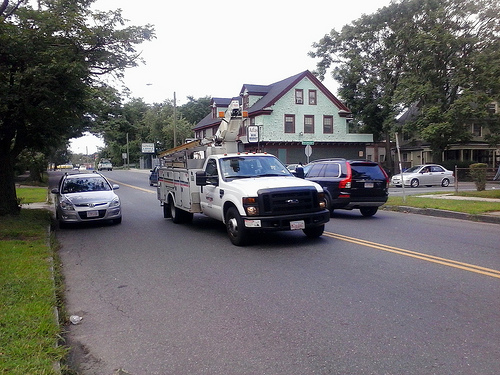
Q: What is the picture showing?
A: It is showing a road.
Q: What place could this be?
A: It is a road.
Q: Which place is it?
A: It is a road.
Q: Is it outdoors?
A: Yes, it is outdoors.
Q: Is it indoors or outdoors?
A: It is outdoors.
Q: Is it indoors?
A: No, it is outdoors.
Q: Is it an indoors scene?
A: No, it is outdoors.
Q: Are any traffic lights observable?
A: No, there are no traffic lights.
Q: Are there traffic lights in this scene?
A: No, there are no traffic lights.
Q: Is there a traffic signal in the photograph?
A: No, there are no traffic lights.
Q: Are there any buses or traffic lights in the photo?
A: No, there are no traffic lights or buses.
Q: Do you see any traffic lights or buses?
A: No, there are no traffic lights or buses.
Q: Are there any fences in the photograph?
A: No, there are no fences.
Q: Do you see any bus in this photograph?
A: No, there are no buses.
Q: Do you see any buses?
A: No, there are no buses.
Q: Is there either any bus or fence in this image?
A: No, there are no buses or fences.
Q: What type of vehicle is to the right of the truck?
A: The vehicle is a car.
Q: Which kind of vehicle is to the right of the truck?
A: The vehicle is a car.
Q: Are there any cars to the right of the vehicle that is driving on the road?
A: Yes, there is a car to the right of the truck.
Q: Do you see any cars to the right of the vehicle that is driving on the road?
A: Yes, there is a car to the right of the truck.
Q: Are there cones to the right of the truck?
A: No, there is a car to the right of the truck.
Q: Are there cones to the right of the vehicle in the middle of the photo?
A: No, there is a car to the right of the truck.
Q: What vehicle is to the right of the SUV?
A: The vehicle is a car.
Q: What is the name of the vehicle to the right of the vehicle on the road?
A: The vehicle is a car.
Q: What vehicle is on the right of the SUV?
A: The vehicle is a car.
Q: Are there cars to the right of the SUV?
A: Yes, there is a car to the right of the SUV.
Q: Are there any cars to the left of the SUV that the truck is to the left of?
A: No, the car is to the right of the SUV.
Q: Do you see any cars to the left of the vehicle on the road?
A: No, the car is to the right of the SUV.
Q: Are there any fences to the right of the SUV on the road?
A: No, there is a car to the right of the SUV.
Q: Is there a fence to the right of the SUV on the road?
A: No, there is a car to the right of the SUV.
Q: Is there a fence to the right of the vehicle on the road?
A: No, there is a car to the right of the SUV.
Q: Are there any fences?
A: No, there are no fences.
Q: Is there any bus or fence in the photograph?
A: No, there are no fences or buses.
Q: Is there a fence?
A: No, there are no fences.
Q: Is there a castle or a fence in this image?
A: No, there are no fences or castles.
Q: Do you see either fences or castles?
A: No, there are no fences or castles.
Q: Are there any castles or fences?
A: No, there are no fences or castles.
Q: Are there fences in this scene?
A: No, there are no fences.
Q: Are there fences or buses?
A: No, there are no fences or buses.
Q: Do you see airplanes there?
A: No, there are no airplanes.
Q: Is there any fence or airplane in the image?
A: No, there are no airplanes or fences.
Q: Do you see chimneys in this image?
A: No, there are no chimneys.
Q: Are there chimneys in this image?
A: No, there are no chimneys.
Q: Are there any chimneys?
A: No, there are no chimneys.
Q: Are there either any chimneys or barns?
A: No, there are no chimneys or barns.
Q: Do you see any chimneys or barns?
A: No, there are no chimneys or barns.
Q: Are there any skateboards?
A: No, there are no skateboards.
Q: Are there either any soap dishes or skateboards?
A: No, there are no skateboards or soap dishes.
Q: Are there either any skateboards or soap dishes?
A: No, there are no skateboards or soap dishes.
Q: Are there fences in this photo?
A: No, there are no fences.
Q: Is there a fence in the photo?
A: No, there are no fences.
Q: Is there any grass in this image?
A: Yes, there is grass.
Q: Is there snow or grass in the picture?
A: Yes, there is grass.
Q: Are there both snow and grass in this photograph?
A: No, there is grass but no snow.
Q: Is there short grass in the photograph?
A: Yes, there is short grass.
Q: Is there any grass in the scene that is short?
A: Yes, there is grass that is short.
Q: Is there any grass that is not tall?
A: Yes, there is short grass.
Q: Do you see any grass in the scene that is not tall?
A: Yes, there is short grass.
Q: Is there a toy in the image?
A: No, there are no toys.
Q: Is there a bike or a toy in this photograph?
A: No, there are no toys or bikes.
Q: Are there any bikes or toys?
A: No, there are no toys or bikes.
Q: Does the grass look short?
A: Yes, the grass is short.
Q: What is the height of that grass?
A: The grass is short.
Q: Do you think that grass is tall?
A: No, the grass is short.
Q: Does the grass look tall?
A: No, the grass is short.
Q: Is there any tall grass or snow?
A: No, there is grass but it is short.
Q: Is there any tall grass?
A: No, there is grass but it is short.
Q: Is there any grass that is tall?
A: No, there is grass but it is short.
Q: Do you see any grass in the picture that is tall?
A: No, there is grass but it is short.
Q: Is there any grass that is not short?
A: No, there is grass but it is short.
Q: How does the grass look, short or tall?
A: The grass is short.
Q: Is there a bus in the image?
A: No, there are no buses.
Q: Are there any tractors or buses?
A: No, there are no buses or tractors.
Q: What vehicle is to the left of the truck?
A: The vehicle is a car.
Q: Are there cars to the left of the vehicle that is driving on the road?
A: Yes, there is a car to the left of the truck.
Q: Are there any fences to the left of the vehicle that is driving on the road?
A: No, there is a car to the left of the truck.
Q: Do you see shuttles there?
A: No, there are no shuttles.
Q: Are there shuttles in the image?
A: No, there are no shuttles.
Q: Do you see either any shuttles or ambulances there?
A: No, there are no shuttles or ambulances.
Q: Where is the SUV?
A: The SUV is on the road.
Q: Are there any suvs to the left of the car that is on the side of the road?
A: Yes, there is a SUV to the left of the car.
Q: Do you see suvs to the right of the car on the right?
A: No, the SUV is to the left of the car.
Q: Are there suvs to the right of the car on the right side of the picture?
A: No, the SUV is to the left of the car.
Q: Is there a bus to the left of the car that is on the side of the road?
A: No, there is a SUV to the left of the car.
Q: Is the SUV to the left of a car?
A: Yes, the SUV is to the left of a car.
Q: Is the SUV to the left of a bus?
A: No, the SUV is to the left of a car.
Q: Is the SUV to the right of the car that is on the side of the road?
A: No, the SUV is to the left of the car.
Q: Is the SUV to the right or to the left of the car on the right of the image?
A: The SUV is to the left of the car.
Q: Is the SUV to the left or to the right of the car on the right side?
A: The SUV is to the left of the car.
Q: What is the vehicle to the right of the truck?
A: The vehicle is a SUV.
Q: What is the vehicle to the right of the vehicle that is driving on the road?
A: The vehicle is a SUV.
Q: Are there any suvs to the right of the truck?
A: Yes, there is a SUV to the right of the truck.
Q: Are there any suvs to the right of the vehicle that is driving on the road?
A: Yes, there is a SUV to the right of the truck.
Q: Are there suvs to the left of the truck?
A: No, the SUV is to the right of the truck.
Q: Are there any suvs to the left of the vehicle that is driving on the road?
A: No, the SUV is to the right of the truck.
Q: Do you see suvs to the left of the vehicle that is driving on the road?
A: No, the SUV is to the right of the truck.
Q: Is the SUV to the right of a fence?
A: No, the SUV is to the right of the truck.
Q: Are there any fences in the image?
A: No, there are no fences.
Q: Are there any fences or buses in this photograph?
A: No, there are no fences or buses.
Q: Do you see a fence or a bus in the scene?
A: No, there are no fences or buses.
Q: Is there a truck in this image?
A: Yes, there is a truck.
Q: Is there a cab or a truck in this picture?
A: Yes, there is a truck.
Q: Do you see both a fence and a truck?
A: No, there is a truck but no fences.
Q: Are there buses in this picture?
A: No, there are no buses.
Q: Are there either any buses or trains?
A: No, there are no buses or trains.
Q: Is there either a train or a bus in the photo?
A: No, there are no buses or trains.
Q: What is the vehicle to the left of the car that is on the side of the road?
A: The vehicle is a truck.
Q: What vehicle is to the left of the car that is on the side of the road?
A: The vehicle is a truck.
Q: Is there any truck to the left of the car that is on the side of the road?
A: Yes, there is a truck to the left of the car.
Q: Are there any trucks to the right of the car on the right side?
A: No, the truck is to the left of the car.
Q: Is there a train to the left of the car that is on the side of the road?
A: No, there is a truck to the left of the car.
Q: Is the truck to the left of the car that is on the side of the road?
A: Yes, the truck is to the left of the car.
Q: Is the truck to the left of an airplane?
A: No, the truck is to the left of the car.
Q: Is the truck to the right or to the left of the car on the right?
A: The truck is to the left of the car.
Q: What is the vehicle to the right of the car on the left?
A: The vehicle is a truck.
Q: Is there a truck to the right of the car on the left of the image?
A: Yes, there is a truck to the right of the car.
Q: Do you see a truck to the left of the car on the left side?
A: No, the truck is to the right of the car.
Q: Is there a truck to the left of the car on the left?
A: No, the truck is to the right of the car.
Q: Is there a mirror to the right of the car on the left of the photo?
A: No, there is a truck to the right of the car.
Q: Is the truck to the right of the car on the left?
A: Yes, the truck is to the right of the car.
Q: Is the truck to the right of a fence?
A: No, the truck is to the right of the car.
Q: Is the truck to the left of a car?
A: No, the truck is to the right of a car.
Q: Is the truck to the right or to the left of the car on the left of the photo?
A: The truck is to the right of the car.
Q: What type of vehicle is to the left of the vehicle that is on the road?
A: The vehicle is a truck.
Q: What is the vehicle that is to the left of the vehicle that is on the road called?
A: The vehicle is a truck.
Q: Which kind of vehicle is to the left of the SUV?
A: The vehicle is a truck.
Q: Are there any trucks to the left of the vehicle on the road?
A: Yes, there is a truck to the left of the SUV.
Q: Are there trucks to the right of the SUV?
A: No, the truck is to the left of the SUV.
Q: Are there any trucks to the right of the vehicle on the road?
A: No, the truck is to the left of the SUV.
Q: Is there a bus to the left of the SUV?
A: No, there is a truck to the left of the SUV.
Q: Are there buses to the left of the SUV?
A: No, there is a truck to the left of the SUV.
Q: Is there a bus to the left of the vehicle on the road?
A: No, there is a truck to the left of the SUV.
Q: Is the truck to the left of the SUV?
A: Yes, the truck is to the left of the SUV.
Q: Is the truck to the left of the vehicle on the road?
A: Yes, the truck is to the left of the SUV.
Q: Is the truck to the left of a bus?
A: No, the truck is to the left of the SUV.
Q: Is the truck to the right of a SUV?
A: No, the truck is to the left of a SUV.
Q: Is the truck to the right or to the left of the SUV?
A: The truck is to the left of the SUV.